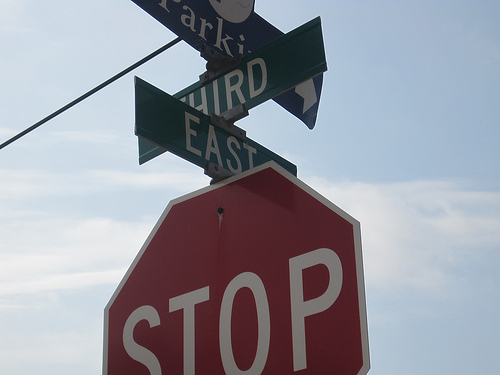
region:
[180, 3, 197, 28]
white letter on sign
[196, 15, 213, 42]
white letter on sign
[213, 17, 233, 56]
white letter on sign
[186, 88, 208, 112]
white letter on sign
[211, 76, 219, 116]
white letter on sign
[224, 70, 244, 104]
white letter on sign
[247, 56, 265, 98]
white letter on sign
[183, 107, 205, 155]
white letter on sign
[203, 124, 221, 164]
white letter on sign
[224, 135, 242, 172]
white letter on sign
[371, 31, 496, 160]
this is the sky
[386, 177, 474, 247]
this is the clouds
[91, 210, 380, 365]
this is a signpost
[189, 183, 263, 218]
the signpost is red in color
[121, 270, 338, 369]
this is a writing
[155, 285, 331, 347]
the writing is in white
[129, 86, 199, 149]
the signpost is green in color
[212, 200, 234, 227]
this is a nut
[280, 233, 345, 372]
This is a letter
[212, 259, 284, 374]
This is a letter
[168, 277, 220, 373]
This is a letter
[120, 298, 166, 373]
This is a letter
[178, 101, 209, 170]
This is a letter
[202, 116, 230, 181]
This is a letter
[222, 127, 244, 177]
This is a letter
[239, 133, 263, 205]
This is a letter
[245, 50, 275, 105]
This is a letter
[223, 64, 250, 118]
This is a letter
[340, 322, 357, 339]
Red and white stop sign in the sky.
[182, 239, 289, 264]
Red and white stop sign in the sky.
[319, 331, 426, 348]
Red and white stop sign in the sky.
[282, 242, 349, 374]
The letter is white.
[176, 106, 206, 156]
The letter is white.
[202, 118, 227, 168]
The letter is white.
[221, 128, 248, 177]
The letter is white.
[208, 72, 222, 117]
The letter is white.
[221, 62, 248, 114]
The letter is white.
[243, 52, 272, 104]
The letter is white.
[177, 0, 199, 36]
The letter is white.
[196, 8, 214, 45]
The letter is white.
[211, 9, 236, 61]
The letter is white.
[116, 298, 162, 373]
A letter on a sign.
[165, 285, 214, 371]
A letter on a sign.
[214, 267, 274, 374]
A letter on a sign.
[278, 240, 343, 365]
A letter on a sign.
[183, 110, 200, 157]
A letter on a sign.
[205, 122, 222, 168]
A letter on a sign.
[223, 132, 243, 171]
A letter on a sign.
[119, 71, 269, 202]
a sign on the pole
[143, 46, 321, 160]
a sign on the pole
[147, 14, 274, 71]
a sign on the pole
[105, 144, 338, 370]
a sign on a metal pole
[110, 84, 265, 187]
a sign on a metal pole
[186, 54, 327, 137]
a sign on a metal pole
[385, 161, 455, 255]
a white fluffy cloud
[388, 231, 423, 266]
a white fluffy cloud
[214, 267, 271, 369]
A letter on a sign.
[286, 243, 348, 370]
A letter on a sign.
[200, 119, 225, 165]
A letter on a sign.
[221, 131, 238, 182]
A letter on a sign.